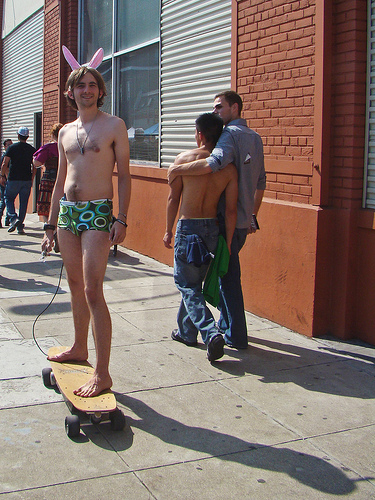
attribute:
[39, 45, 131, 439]
man — bare foot, barefoot, shirtless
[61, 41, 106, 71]
bunny ears — pink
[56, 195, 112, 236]
swimsuit — gree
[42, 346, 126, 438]
skateboard — brown, wooden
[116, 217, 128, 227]
wristband — dark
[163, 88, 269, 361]
couple — walking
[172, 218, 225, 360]
pants — blue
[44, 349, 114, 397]
foot — bare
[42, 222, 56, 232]
watch — black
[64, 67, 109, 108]
hair — long, brown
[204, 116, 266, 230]
shirt — blue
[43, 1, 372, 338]
brick — orange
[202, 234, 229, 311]
shirt — green